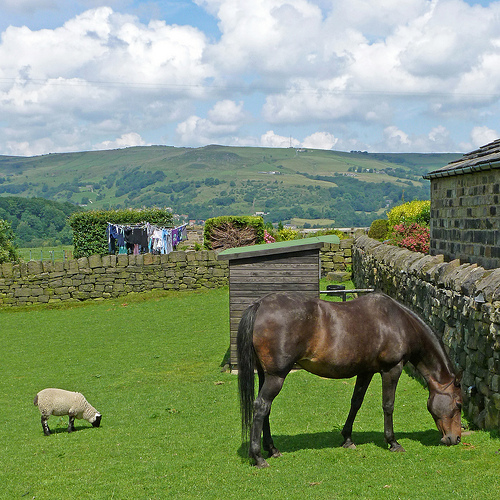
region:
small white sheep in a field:
[24, 380, 109, 440]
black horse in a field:
[223, 289, 471, 473]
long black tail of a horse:
[230, 298, 263, 468]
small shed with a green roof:
[215, 230, 350, 376]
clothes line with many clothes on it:
[95, 216, 193, 258]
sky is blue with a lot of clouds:
[0, 2, 497, 160]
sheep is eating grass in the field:
[27, 385, 108, 439]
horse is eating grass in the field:
[227, 288, 474, 472]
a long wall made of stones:
[0, 241, 235, 322]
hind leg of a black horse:
[238, 312, 311, 470]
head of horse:
[417, 383, 476, 462]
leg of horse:
[243, 357, 279, 468]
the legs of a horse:
[342, 366, 408, 466]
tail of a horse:
[217, 306, 277, 446]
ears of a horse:
[434, 366, 469, 393]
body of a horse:
[215, 268, 407, 377]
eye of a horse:
[442, 402, 467, 419]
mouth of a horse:
[437, 428, 469, 450]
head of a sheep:
[87, 396, 110, 427]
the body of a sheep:
[31, 370, 83, 421]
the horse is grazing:
[228, 278, 467, 461]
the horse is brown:
[231, 284, 481, 479]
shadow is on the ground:
[282, 430, 329, 450]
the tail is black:
[234, 323, 264, 405]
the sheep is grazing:
[34, 386, 116, 434]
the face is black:
[94, 416, 103, 425]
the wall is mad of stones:
[91, 262, 226, 286]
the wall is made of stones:
[431, 186, 492, 261]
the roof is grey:
[439, 148, 495, 166]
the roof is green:
[236, 233, 338, 239]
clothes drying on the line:
[94, 201, 218, 266]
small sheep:
[8, 365, 117, 453]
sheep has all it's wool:
[25, 383, 118, 445]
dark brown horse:
[235, 278, 477, 465]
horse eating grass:
[355, 284, 495, 459]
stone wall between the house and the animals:
[358, 221, 498, 446]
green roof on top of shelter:
[216, 224, 337, 264]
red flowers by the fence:
[383, 218, 438, 259]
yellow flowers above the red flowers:
[379, 186, 459, 227]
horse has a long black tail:
[225, 305, 263, 442]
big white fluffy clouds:
[45, 25, 223, 119]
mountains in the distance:
[122, 138, 210, 198]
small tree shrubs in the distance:
[242, 165, 287, 196]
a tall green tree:
[70, 209, 122, 257]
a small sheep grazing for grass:
[25, 373, 110, 443]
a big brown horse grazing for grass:
[184, 295, 469, 456]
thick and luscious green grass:
[134, 369, 225, 477]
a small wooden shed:
[201, 212, 332, 317]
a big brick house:
[424, 146, 498, 291]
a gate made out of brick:
[355, 222, 497, 390]